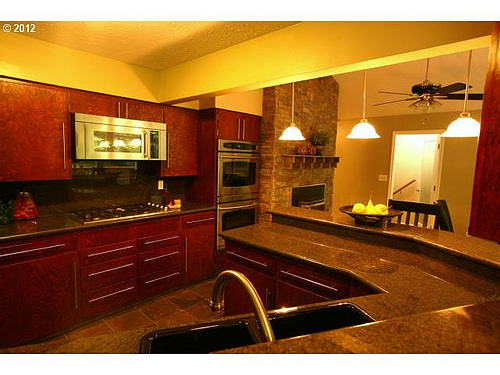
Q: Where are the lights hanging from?
A: The ceiling.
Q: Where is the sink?
A: In the kitchen.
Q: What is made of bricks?
A: The fireplace.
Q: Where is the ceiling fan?
A: On the ceiling.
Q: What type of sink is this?
A: Double.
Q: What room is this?
A: Kitchen.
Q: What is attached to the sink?
A: A faucet.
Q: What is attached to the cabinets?
A: Microwave.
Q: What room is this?
A: A kitchen.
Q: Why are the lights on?
A: To illuminate the room.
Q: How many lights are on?
A: Three.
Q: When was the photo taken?
A: In the evening.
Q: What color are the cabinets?
A: Brown.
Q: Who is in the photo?
A: Nobody.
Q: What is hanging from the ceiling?
A: A fan.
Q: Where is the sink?
A: On the counter.